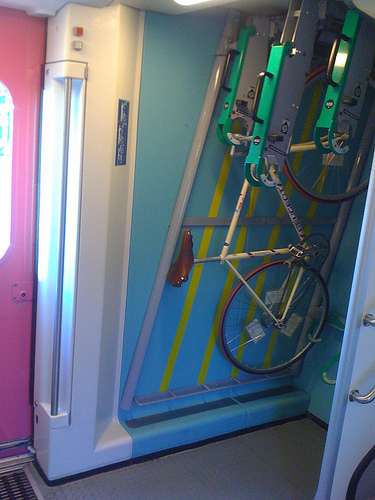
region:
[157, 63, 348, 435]
A brown bicycle hanging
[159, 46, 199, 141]
A blue store wall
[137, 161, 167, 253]
A blue store wall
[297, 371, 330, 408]
A blue store wall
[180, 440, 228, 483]
A grey store floor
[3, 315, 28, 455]
A pink house door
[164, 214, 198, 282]
A brown bicyle seat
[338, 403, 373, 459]
A grey store door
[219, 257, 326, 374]
the rear tire of the bike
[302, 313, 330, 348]
the green hook on the bike tire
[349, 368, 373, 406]
the rail on the wall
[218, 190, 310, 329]
the white frame of the bike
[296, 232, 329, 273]
the gear on the bike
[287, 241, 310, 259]
the etal pedal of the bike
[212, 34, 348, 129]
the black handles on the hanging object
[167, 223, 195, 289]
the seat of the bike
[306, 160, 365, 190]
the spokes of the tire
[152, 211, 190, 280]
this is made of metal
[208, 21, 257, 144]
this is made of metal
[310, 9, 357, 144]
this is made of metal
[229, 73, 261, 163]
this is made of metal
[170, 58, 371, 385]
THIS IS A BIKE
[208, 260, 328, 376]
THE WHEEL OF A BIKE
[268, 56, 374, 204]
THE WHEEL OF A BIKE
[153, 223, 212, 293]
THE SEAT OF A BIKE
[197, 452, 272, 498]
THE FLOOR IS GREY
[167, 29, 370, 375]
a bicycle hanging from a rack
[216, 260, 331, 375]
the rear wheel of a bicycle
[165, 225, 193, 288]
the seat of a bicycle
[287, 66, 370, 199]
the front wheel of a bicycle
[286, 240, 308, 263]
the pedal of a bicycle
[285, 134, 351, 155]
the front fork of a bicycle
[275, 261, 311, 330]
the chain of a bicycle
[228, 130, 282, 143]
the handle bars of a bicycle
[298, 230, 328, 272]
the chainring of a bicycle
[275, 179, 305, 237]
the brand name of a bicycle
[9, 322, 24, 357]
Part of the door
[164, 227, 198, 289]
The seat of the bicycle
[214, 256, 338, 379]
The back wheel of the bicycle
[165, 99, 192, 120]
Part of the wall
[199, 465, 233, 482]
Part of the ground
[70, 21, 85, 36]
A red light on the wall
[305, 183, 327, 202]
Part of the front tire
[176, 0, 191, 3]
Part of the light on the ceiling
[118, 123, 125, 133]
Part of the blue sign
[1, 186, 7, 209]
Part of the window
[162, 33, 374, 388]
a vertical bike parking slot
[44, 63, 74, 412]
a tall steel post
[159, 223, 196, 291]
an orange bike seat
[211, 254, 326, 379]
a rear wheel of a bike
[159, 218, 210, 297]
a brown colored bicycle seat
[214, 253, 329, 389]
rear wheel of a bike